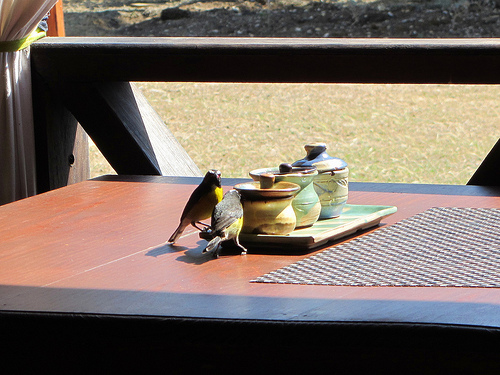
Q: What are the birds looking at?
A: Jars.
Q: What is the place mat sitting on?
A: A table.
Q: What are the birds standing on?
A: A table.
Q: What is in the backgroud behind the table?
A: A grassy field.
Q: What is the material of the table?
A: Wood.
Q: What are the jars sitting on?
A: A plate.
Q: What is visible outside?
A: The ground.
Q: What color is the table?
A: A dark brown.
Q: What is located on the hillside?
A: Grass.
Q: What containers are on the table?
A: Three little wooden containers.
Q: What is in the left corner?
A: Edge of curtain with green tieback.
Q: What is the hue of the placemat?
A: Light and dark patterned.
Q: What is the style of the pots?
A: Three little multi-colored pots.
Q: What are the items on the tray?
A: Three decorative containers.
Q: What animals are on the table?
A: Two birds on a table.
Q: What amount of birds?
A: Two.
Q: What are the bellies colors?
A: Yellow.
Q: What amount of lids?
A: Three.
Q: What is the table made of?
A: Wood.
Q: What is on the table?
A: Crockery.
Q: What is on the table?
A: Placemat.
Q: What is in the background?
A: Dirt.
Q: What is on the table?
A: Jars and birds.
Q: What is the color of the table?
A: Brown.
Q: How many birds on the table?
A: Two.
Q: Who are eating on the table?
A: No one.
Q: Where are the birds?
A: On the table.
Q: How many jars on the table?
A: Three.